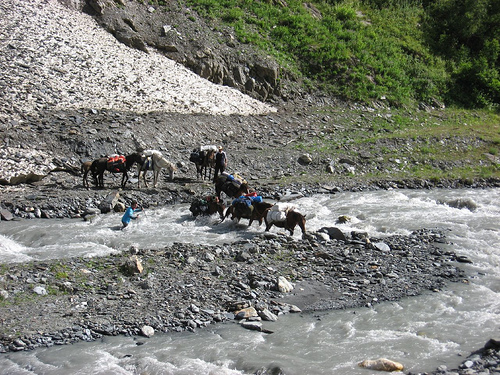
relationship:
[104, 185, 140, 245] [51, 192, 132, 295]
man next to river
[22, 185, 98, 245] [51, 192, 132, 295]
rock in river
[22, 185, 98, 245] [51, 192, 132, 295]
rock on riverbed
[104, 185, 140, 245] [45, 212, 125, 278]
person in water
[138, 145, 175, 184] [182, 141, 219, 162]
horse has baby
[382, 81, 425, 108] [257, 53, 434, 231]
bush on ground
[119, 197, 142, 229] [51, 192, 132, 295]
man in river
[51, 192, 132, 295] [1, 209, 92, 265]
river has currents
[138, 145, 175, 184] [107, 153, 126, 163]
horse has bag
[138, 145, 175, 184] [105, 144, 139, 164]
horse has bag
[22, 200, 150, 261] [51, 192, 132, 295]
pebbles on river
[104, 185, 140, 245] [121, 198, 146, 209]
man has hat